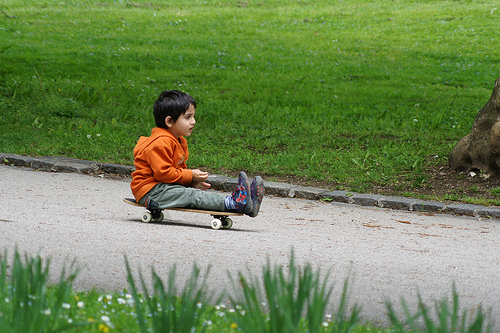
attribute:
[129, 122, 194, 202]
sweatshirt — orange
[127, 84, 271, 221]
boy — little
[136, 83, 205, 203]
boy — little 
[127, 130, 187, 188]
hoodie — orange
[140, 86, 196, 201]
boy — little 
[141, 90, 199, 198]
boy — little 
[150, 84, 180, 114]
hair — black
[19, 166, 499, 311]
path — gray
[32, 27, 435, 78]
grass — lush, green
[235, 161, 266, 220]
sneakers — gray 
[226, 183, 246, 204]
shoelaces — blue, pink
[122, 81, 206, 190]
boy — small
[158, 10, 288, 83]
flowers — white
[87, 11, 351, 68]
grass — green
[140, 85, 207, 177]
boy — small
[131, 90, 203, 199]
boy — small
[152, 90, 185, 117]
hair — black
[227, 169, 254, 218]
shoe — small, blue, red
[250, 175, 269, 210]
shoe — red, blue, small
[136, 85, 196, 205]
boy — small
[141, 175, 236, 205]
pants — green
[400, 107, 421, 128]
flower — white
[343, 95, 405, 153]
grass — green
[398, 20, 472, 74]
grass — green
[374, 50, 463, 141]
flowers — white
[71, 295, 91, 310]
flower — white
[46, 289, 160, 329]
grass — green